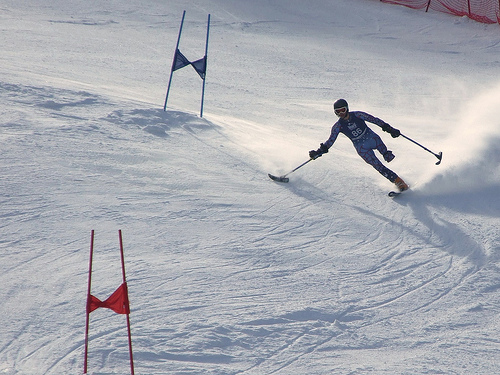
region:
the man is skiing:
[259, 97, 494, 284]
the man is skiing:
[292, 40, 442, 260]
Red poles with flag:
[53, 221, 153, 373]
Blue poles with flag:
[141, 0, 226, 125]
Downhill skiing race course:
[60, 9, 471, 369]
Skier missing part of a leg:
[256, 82, 456, 218]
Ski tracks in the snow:
[166, 212, 465, 357]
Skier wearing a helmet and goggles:
[317, 87, 414, 195]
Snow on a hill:
[0, 17, 260, 269]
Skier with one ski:
[254, 91, 448, 216]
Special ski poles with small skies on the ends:
[238, 123, 480, 218]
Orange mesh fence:
[401, 0, 496, 38]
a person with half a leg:
[295, 82, 452, 219]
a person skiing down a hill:
[261, 84, 447, 233]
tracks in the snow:
[196, 213, 436, 289]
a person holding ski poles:
[268, 74, 460, 206]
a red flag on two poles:
[44, 205, 149, 355]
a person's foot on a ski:
[353, 156, 425, 227]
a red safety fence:
[380, 2, 487, 23]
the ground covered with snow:
[73, 144, 365, 240]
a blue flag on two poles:
[127, 28, 226, 138]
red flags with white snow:
[48, 214, 136, 373]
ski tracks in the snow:
[282, 244, 439, 366]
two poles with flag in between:
[44, 200, 146, 372]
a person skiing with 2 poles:
[251, 72, 460, 224]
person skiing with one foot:
[307, 120, 457, 255]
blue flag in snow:
[68, 5, 230, 167]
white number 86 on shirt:
[338, 112, 375, 155]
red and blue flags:
[78, 62, 220, 372]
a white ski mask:
[306, 88, 368, 128]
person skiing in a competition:
[22, 68, 442, 365]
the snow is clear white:
[276, 311, 308, 331]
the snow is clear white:
[294, 324, 328, 362]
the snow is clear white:
[295, 298, 319, 325]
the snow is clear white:
[257, 308, 283, 332]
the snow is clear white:
[262, 298, 284, 323]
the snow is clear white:
[248, 361, 271, 369]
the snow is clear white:
[279, 298, 305, 323]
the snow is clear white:
[286, 361, 311, 373]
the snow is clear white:
[286, 318, 313, 343]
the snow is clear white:
[266, 317, 286, 333]